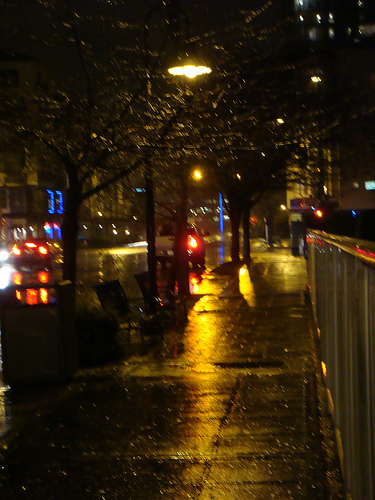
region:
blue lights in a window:
[40, 185, 57, 216]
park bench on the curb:
[93, 271, 160, 337]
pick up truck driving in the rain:
[143, 211, 207, 264]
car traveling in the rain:
[8, 228, 68, 275]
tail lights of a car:
[9, 236, 47, 255]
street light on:
[185, 161, 206, 184]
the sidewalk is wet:
[179, 290, 321, 477]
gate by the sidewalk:
[313, 263, 373, 467]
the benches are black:
[100, 279, 154, 336]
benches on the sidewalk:
[100, 268, 185, 349]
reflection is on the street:
[13, 282, 65, 329]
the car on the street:
[15, 239, 70, 267]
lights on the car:
[12, 243, 46, 256]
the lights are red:
[12, 245, 50, 256]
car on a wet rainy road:
[9, 233, 67, 265]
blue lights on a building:
[39, 184, 70, 212]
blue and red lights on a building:
[45, 221, 66, 236]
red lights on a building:
[308, 196, 328, 220]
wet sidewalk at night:
[202, 286, 305, 477]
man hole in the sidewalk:
[220, 351, 285, 375]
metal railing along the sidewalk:
[307, 227, 367, 482]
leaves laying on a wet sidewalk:
[262, 426, 297, 483]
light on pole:
[148, 47, 204, 96]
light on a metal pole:
[161, 49, 252, 119]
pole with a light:
[159, 34, 222, 99]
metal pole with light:
[140, 28, 242, 123]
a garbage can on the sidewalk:
[3, 264, 118, 424]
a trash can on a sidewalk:
[7, 264, 102, 375]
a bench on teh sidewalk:
[96, 283, 141, 328]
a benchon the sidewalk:
[135, 263, 208, 338]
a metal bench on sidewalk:
[96, 278, 152, 325]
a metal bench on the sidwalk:
[128, 264, 186, 309]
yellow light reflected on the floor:
[187, 269, 264, 443]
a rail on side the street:
[302, 223, 374, 480]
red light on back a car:
[181, 215, 207, 272]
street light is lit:
[171, 150, 206, 195]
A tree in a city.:
[88, 24, 181, 341]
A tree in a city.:
[133, 45, 224, 316]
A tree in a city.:
[202, 27, 296, 266]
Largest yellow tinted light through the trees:
[168, 65, 211, 77]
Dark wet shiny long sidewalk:
[1, 256, 343, 497]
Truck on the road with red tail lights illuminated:
[150, 222, 208, 269]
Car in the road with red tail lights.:
[10, 238, 61, 266]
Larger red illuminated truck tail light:
[189, 236, 197, 248]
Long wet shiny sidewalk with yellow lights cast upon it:
[3, 254, 338, 493]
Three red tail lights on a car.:
[12, 242, 46, 255]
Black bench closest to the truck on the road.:
[133, 272, 188, 324]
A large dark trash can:
[2, 280, 78, 383]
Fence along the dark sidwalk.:
[303, 227, 373, 499]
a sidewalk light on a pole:
[138, 51, 213, 313]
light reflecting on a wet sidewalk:
[44, 249, 332, 498]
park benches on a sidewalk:
[99, 274, 188, 351]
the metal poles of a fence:
[300, 228, 373, 492]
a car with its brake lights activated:
[8, 236, 62, 268]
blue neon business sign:
[42, 187, 67, 217]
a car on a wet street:
[6, 234, 65, 276]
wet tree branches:
[60, 46, 317, 163]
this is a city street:
[25, 48, 371, 375]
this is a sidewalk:
[44, 101, 329, 466]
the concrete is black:
[88, 358, 210, 464]